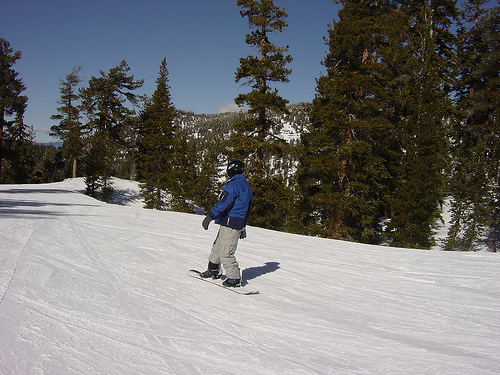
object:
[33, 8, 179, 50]
sky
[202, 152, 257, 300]
person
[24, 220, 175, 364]
snow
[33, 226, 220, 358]
ground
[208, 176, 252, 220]
jacket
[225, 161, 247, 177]
helmet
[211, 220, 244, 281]
pants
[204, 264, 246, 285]
boots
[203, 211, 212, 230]
gloves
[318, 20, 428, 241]
trees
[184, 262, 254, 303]
snowboard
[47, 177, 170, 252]
slope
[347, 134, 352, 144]
bark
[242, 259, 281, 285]
shadow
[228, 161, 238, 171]
emblem